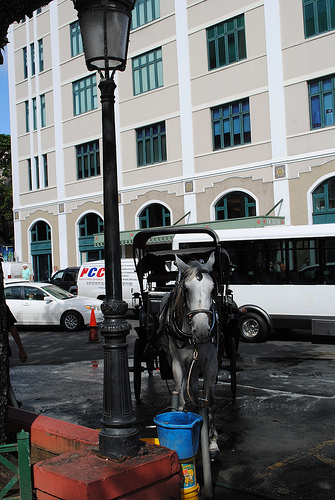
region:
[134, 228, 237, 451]
horse-drawn carriage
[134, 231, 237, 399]
old fashioned black carriage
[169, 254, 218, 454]
a white horse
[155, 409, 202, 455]
a blue bucket sitting on top of a yellow bucket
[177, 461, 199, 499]
a upside down yellow bucket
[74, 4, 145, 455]
a black lamp post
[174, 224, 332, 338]
a white bus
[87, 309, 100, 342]
orange traffic cones by the white car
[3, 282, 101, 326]
a white car behind the bus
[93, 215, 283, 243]
a light green awning on the building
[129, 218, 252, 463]
a white horse pulling a carriage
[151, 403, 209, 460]
a blue bucket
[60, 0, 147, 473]
a black lamppost with a fancy light on the top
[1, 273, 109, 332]
a white car with a person clearly visible in the front seat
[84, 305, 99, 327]
an orange traffic cone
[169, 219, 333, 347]
a white bus with tinted windows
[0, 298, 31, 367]
a person's extended arm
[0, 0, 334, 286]
a beige and white building with windows framed in green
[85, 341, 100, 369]
the reflection of an orange traffic cone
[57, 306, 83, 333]
the front tire of a white car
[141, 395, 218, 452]
A blue bucket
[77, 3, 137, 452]
A black lamp pole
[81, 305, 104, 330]
An orange cone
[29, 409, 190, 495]
A wall made of brick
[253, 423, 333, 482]
Yellow lines on the ground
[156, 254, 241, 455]
A horse pulling a carriage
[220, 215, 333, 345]
A white bus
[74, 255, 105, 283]
A van that says PCC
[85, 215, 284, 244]
A green awning in front of a building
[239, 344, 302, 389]
The ground is wet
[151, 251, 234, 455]
Horse on the sidewalk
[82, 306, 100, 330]
Cone in the street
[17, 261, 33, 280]
Man wearing a green shirt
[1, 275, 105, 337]
White car on the street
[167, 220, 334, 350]
Bus on the street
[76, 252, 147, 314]
Van on the street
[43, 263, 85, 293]
Truck near the curb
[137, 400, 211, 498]
Buckets on the sidewalk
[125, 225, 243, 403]
Carriage behind the horse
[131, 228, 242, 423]
white horse attached to carriage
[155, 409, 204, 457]
blue bucket of water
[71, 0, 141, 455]
a black metal light post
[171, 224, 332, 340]
white bus on street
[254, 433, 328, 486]
yellow painted lines on street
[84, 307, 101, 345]
orange traffic cone in street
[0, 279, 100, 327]
small white car driving on street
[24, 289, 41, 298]
passenger in car window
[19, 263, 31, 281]
man with white hat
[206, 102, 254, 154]
window on building with shades partially pulled down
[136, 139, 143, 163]
glass window on the building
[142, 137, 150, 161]
glass window on the building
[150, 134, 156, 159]
glass window on the building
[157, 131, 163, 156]
glass window on the building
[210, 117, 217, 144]
glass window on the building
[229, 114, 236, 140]
glass window on the building